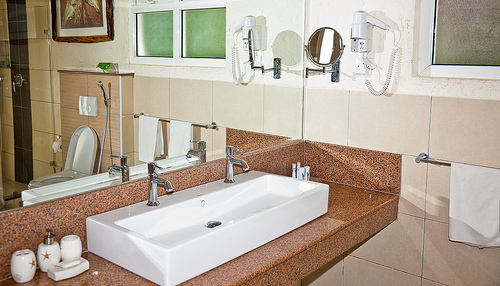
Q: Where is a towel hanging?
A: On rack.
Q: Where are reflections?
A: In the mirror.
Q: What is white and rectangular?
A: The sink.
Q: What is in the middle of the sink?
A: The drain.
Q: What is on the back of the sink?
A: A mirror.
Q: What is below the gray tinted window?
A: Towel on a rack.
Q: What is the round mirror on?
A: The wall.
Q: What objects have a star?
A: Soap dishes.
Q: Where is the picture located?
A: Above the toliet.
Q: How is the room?
A: Clear.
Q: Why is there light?
A: Vision.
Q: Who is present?
A: No one.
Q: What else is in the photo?
A: Taps.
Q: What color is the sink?
A: White.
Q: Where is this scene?
A: In a bathroom.